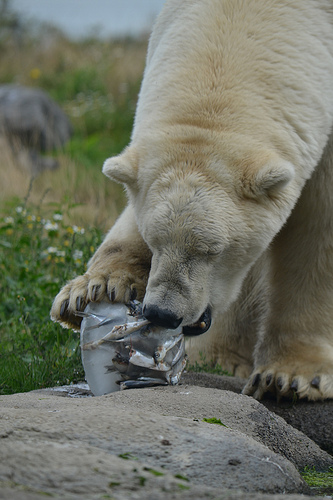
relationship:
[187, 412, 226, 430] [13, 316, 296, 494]
moss on rock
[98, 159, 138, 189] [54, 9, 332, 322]
ear of bear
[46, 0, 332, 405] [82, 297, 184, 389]
bear eating fish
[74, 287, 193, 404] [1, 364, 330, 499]
ice on rock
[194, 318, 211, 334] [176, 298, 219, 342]
tooth in mouth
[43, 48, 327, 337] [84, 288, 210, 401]
bear eating som fish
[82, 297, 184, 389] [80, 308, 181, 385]
fish trapped in ice